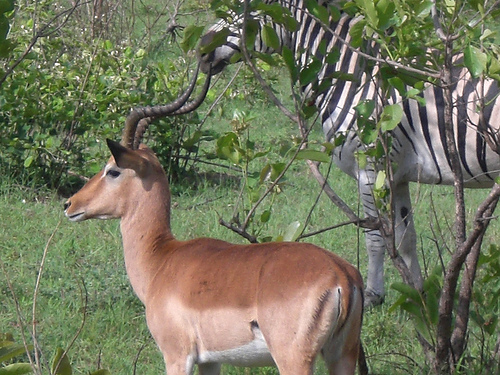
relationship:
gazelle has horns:
[46, 74, 361, 366] [131, 68, 218, 133]